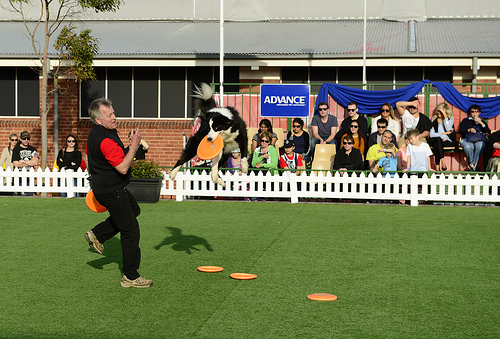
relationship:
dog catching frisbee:
[185, 87, 250, 165] [194, 138, 224, 160]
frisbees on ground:
[190, 249, 348, 317] [313, 226, 379, 250]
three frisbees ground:
[183, 260, 346, 307] [175, 260, 259, 286]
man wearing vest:
[81, 85, 146, 208] [83, 128, 119, 190]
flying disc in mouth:
[196, 133, 223, 159] [212, 136, 225, 140]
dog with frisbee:
[185, 87, 250, 165] [194, 138, 224, 160]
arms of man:
[119, 142, 136, 181] [75, 94, 157, 336]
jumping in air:
[215, 143, 245, 157] [141, 4, 174, 71]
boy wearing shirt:
[380, 155, 401, 171] [382, 153, 392, 165]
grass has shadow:
[0, 194, 499, 339] [150, 216, 218, 259]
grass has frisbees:
[255, 217, 318, 235] [229, 272, 256, 280]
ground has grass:
[313, 226, 379, 250] [255, 217, 318, 235]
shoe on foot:
[109, 271, 159, 290] [83, 225, 105, 259]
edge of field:
[487, 209, 499, 227] [299, 217, 487, 274]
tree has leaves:
[9, 3, 37, 17] [25, 2, 35, 8]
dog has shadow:
[185, 87, 250, 165] [150, 216, 218, 259]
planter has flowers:
[137, 168, 160, 203] [133, 162, 158, 177]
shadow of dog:
[189, 238, 218, 252] [185, 87, 250, 165]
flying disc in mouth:
[204, 133, 227, 159] [212, 136, 225, 140]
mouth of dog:
[200, 129, 217, 138] [185, 87, 250, 165]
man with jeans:
[81, 85, 146, 208] [91, 187, 141, 280]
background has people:
[25, 17, 59, 131] [378, 103, 450, 152]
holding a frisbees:
[127, 129, 144, 142] [229, 272, 256, 280]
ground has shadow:
[313, 226, 379, 250] [77, 246, 122, 273]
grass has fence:
[0, 194, 499, 339] [12, 171, 88, 197]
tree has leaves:
[0, 0, 116, 168] [84, 3, 120, 17]